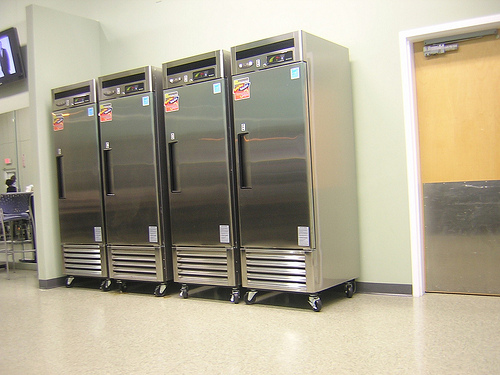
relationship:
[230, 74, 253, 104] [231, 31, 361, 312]
picture on fridge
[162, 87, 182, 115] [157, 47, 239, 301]
picture on fridge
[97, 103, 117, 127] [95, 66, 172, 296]
picture on fridge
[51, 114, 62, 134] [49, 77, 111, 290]
picture on fridge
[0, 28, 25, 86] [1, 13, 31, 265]
television mounted on wall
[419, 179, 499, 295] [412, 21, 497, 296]
bottom of door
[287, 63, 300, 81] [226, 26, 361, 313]
logo on refrigerator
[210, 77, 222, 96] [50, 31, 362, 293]
logo on fridge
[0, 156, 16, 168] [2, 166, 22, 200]
exit sign above door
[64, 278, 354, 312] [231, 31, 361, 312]
wheels of fridge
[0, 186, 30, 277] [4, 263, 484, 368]
chair on floor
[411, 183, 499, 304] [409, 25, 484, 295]
metal on door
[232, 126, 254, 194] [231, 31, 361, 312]
handle of fridge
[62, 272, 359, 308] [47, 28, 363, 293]
wheels on machines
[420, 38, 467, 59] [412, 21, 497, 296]
hinge on door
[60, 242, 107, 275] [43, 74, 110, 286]
vent on machine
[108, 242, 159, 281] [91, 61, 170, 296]
vent on machine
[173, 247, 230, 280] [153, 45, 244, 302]
vent on machine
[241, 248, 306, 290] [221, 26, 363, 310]
vent on machine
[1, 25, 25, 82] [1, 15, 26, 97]
television on wall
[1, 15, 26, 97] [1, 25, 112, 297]
wall of room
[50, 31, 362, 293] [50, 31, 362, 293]
fridge next fridge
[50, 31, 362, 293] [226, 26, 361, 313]
fridge next refrigerator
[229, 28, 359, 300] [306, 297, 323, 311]
container has wheel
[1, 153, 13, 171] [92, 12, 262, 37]
sign on wall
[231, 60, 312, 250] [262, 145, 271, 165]
door has part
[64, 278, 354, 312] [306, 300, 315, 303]
wheels has part